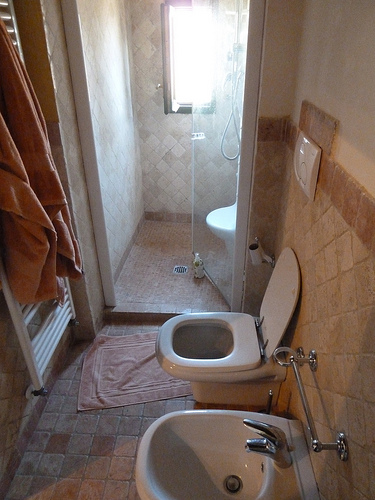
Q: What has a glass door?
A: Shower.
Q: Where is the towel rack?
A: Over sink.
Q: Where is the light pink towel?
A: On floor.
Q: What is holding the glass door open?
A: Bottle.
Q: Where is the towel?
A: On the towel rack.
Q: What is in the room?
A: Toilet.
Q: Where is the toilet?
A: In the room.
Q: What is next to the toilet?
A: Sink.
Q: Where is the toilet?
A: Next to the sink.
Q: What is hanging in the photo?
A: The towel.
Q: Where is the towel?
A: On the floor.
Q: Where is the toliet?
A: Between the sink and shower.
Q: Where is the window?
A: In the shower.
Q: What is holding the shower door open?
A: A bottle.